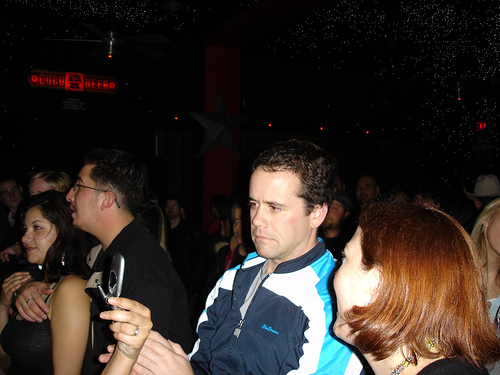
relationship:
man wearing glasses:
[56, 149, 196, 375] [67, 178, 108, 194]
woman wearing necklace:
[313, 182, 498, 375] [383, 336, 441, 374]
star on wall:
[190, 100, 245, 167] [105, 66, 498, 234]